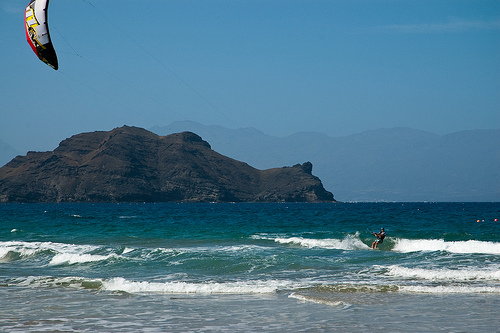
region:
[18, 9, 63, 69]
a parachuat in air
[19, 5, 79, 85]
a parachuat flying in air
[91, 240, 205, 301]
water coming out to earth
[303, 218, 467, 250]
a flow of water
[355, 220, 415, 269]
a man in the water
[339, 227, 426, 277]
a man jumping water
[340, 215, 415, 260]
a man diving in water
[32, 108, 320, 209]
a mountain in the back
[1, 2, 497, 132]
blue of daytime sky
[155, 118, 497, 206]
hazy mountains on horizon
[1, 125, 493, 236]
rocky mountain in ocean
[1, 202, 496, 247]
rough surface of ocean water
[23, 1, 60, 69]
parasail flying in sky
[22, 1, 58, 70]
colored design on parasail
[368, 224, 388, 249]
person leaning back over water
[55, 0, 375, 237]
cables of parasail in the air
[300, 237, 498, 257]
white water of crashing wave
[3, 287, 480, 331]
sea foam on water surface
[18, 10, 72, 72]
a object in air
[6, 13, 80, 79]
a object flying in air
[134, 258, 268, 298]
flow of the water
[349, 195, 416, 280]
a man in water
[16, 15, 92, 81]
a parachuate in air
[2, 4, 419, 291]
a man with parachuate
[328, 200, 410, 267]
a man playing in water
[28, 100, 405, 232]
a big mountain in back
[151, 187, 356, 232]
a clear view of water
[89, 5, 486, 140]
a clear view of sky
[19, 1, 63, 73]
multicolored parafoil in blue sky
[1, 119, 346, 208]
rocky island in ocean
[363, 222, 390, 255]
person parasailing on ocean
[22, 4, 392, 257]
person using black and white parasail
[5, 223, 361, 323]
ocean waves at beach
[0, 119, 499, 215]
rocky island with land in distance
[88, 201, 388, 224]
dark blue ocean water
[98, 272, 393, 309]
small white wave breaking on shore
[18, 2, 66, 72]
inflated parasail with black white and red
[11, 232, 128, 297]
cresting ocean waves at beach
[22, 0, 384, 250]
person is wind surfing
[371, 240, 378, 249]
legs of a human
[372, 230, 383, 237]
arms of a human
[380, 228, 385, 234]
the head of a person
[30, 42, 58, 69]
bottom of kite is black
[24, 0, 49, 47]
center of kite is yellow black and red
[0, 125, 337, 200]
a rocky looking island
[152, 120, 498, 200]
hazy land in distance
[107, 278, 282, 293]
the foam is white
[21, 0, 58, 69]
large black and red kite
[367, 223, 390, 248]
person in water kite surfing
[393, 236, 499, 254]
large wide white crashing wave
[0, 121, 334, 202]
large rocky tall island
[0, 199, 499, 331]
large blue open water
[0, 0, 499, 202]
large open blue sky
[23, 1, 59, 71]
Black, grey, red and yellow kite.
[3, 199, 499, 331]
Blue, white and grey body of water.